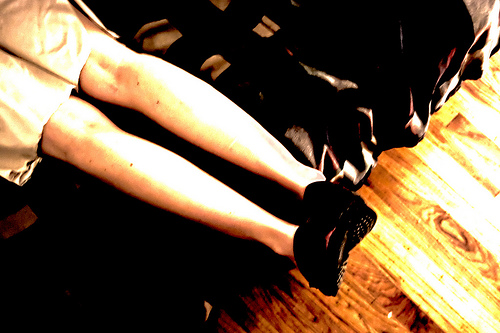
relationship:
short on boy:
[0, 1, 117, 188] [0, 0, 378, 296]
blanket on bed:
[0, 0, 499, 333] [1, 1, 498, 329]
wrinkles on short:
[35, 34, 67, 59] [0, 1, 117, 188]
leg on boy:
[42, 89, 336, 287] [1, 2, 398, 303]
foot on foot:
[289, 215, 351, 297] [283, 212, 362, 313]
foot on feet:
[301, 177, 378, 252] [284, 152, 376, 296]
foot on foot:
[301, 177, 378, 252] [297, 177, 378, 257]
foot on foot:
[289, 215, 351, 297] [291, 222, 346, 293]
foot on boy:
[289, 215, 351, 297] [0, 0, 378, 296]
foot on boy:
[301, 177, 378, 252] [0, 0, 378, 296]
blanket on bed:
[115, 0, 499, 195] [1, 1, 498, 333]